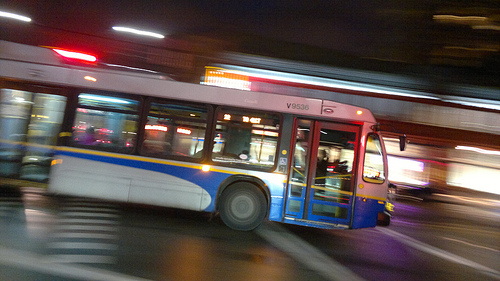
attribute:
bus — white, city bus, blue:
[0, 40, 409, 230]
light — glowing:
[48, 46, 98, 66]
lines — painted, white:
[0, 195, 499, 278]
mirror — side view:
[396, 132, 407, 150]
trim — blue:
[0, 140, 387, 230]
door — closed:
[305, 119, 363, 228]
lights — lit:
[2, 9, 279, 82]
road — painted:
[6, 201, 497, 280]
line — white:
[375, 220, 498, 277]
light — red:
[53, 40, 103, 70]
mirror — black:
[394, 121, 414, 154]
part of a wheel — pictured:
[237, 181, 274, 224]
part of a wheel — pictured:
[214, 178, 273, 200]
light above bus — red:
[40, 32, 109, 79]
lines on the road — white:
[250, 230, 437, 280]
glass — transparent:
[112, 93, 304, 192]